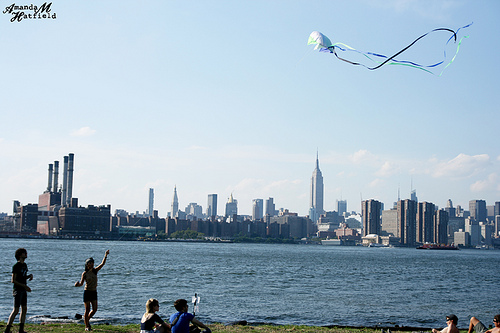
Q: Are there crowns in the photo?
A: No, there are no crowns.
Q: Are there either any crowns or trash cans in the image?
A: No, there are no crowns or trash cans.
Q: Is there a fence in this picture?
A: No, there are no fences.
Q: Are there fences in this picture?
A: No, there are no fences.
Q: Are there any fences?
A: No, there are no fences.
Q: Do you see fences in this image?
A: No, there are no fences.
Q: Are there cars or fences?
A: No, there are no fences or cars.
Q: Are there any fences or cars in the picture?
A: No, there are no fences or cars.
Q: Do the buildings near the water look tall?
A: Yes, the buildings are tall.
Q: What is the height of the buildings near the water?
A: The buildings are tall.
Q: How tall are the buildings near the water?
A: The buildings are tall.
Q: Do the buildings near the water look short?
A: No, the buildings are tall.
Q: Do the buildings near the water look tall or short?
A: The buildings are tall.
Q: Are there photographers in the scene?
A: Yes, there is a photographer.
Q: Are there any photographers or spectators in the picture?
A: Yes, there is a photographer.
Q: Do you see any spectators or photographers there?
A: Yes, there is a photographer.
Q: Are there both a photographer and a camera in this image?
A: No, there is a photographer but no cameras.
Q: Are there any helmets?
A: No, there are no helmets.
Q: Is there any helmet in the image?
A: No, there are no helmets.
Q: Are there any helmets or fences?
A: No, there are no helmets or fences.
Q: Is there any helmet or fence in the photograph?
A: No, there are no helmets or fences.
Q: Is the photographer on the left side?
A: Yes, the photographer is on the left of the image.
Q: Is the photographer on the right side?
A: No, the photographer is on the left of the image.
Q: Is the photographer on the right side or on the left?
A: The photographer is on the left of the image.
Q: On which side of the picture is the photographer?
A: The photographer is on the left of the image.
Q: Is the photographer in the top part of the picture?
A: Yes, the photographer is in the top of the image.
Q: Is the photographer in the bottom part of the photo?
A: No, the photographer is in the top of the image.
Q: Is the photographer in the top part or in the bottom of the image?
A: The photographer is in the top of the image.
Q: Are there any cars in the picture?
A: No, there are no cars.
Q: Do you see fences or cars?
A: No, there are no cars or fences.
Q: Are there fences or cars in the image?
A: No, there are no cars or fences.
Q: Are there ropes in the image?
A: No, there are no ropes.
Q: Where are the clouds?
A: The clouds are in the sky.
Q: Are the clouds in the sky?
A: Yes, the clouds are in the sky.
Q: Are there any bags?
A: No, there are no bags.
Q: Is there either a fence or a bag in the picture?
A: No, there are no bags or fences.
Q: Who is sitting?
A: The people are sitting.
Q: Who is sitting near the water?
A: The people are sitting near the water.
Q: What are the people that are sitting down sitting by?
A: The people are sitting by the water.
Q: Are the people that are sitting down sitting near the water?
A: Yes, the people are sitting near the water.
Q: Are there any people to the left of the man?
A: Yes, there are people to the left of the man.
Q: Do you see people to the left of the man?
A: Yes, there are people to the left of the man.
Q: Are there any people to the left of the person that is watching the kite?
A: Yes, there are people to the left of the man.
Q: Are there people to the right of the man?
A: No, the people are to the left of the man.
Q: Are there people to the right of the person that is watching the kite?
A: No, the people are to the left of the man.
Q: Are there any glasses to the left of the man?
A: No, there are people to the left of the man.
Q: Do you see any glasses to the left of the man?
A: No, there are people to the left of the man.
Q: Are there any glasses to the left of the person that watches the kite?
A: No, there are people to the left of the man.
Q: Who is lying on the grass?
A: The people are lying on the grass.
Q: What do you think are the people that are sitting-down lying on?
A: The people are lying on the grass.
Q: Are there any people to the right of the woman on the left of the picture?
A: Yes, there are people to the right of the woman.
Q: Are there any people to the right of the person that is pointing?
A: Yes, there are people to the right of the woman.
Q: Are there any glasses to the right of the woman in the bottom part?
A: No, there are people to the right of the woman.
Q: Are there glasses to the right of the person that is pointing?
A: No, there are people to the right of the woman.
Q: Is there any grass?
A: Yes, there is grass.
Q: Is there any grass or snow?
A: Yes, there is grass.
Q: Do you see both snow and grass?
A: No, there is grass but no snow.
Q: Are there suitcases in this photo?
A: No, there are no suitcases.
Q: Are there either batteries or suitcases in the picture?
A: No, there are no suitcases or batteries.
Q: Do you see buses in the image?
A: No, there are no buses.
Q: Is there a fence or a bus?
A: No, there are no buses or fences.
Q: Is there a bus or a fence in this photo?
A: No, there are no buses or fences.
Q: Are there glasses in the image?
A: No, there are no glasses.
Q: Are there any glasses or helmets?
A: No, there are no glasses or helmets.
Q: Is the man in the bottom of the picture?
A: Yes, the man is in the bottom of the image.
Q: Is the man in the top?
A: No, the man is in the bottom of the image.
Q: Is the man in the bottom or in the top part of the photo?
A: The man is in the bottom of the image.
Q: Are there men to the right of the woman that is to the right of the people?
A: Yes, there is a man to the right of the woman.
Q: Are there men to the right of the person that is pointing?
A: Yes, there is a man to the right of the woman.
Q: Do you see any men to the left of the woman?
A: No, the man is to the right of the woman.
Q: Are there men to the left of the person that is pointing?
A: No, the man is to the right of the woman.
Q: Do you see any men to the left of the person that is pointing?
A: No, the man is to the right of the woman.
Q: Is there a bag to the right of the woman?
A: No, there is a man to the right of the woman.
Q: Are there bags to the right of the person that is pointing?
A: No, there is a man to the right of the woman.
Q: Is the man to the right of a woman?
A: Yes, the man is to the right of a woman.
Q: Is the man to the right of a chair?
A: No, the man is to the right of a woman.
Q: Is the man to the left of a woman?
A: No, the man is to the right of a woman.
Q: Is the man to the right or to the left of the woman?
A: The man is to the right of the woman.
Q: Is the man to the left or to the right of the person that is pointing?
A: The man is to the right of the woman.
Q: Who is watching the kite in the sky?
A: The man is watching the kite.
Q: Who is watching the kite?
A: The man is watching the kite.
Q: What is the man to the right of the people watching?
A: The man is watching the kite.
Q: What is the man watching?
A: The man is watching the kite.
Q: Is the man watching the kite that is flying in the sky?
A: Yes, the man is watching the kite.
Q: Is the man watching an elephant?
A: No, the man is watching the kite.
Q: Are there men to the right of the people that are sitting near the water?
A: Yes, there is a man to the right of the people.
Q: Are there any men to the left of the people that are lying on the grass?
A: No, the man is to the right of the people.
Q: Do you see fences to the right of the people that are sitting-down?
A: No, there is a man to the right of the people.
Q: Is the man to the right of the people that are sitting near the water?
A: Yes, the man is to the right of the people.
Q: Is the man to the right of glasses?
A: No, the man is to the right of the people.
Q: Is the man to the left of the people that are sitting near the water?
A: No, the man is to the right of the people.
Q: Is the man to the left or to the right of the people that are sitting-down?
A: The man is to the right of the people.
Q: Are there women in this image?
A: Yes, there is a woman.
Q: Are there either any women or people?
A: Yes, there is a woman.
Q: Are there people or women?
A: Yes, there is a woman.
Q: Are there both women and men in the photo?
A: Yes, there are both a woman and a man.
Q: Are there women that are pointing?
A: Yes, there is a woman that is pointing.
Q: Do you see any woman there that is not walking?
A: Yes, there is a woman that is pointing .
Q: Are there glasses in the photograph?
A: No, there are no glasses.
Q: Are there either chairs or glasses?
A: No, there are no glasses or chairs.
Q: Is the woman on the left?
A: Yes, the woman is on the left of the image.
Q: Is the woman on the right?
A: No, the woman is on the left of the image.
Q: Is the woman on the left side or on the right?
A: The woman is on the left of the image.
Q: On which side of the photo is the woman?
A: The woman is on the left of the image.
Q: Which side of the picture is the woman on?
A: The woman is on the left of the image.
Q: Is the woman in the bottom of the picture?
A: Yes, the woman is in the bottom of the image.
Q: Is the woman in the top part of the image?
A: No, the woman is in the bottom of the image.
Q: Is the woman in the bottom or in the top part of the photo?
A: The woman is in the bottom of the image.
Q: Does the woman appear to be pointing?
A: Yes, the woman is pointing.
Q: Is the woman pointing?
A: Yes, the woman is pointing.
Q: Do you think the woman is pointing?
A: Yes, the woman is pointing.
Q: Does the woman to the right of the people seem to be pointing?
A: Yes, the woman is pointing.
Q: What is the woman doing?
A: The woman is pointing.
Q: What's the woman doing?
A: The woman is pointing.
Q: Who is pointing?
A: The woman is pointing.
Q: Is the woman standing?
A: No, the woman is pointing.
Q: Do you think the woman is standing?
A: No, the woman is pointing.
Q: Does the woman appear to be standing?
A: No, the woman is pointing.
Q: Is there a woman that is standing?
A: No, there is a woman but she is pointing.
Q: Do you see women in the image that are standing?
A: No, there is a woman but she is pointing.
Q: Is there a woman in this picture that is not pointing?
A: No, there is a woman but she is pointing.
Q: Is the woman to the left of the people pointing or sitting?
A: The woman is pointing.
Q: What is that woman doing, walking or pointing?
A: The woman is pointing.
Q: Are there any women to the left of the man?
A: Yes, there is a woman to the left of the man.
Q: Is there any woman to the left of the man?
A: Yes, there is a woman to the left of the man.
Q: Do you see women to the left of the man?
A: Yes, there is a woman to the left of the man.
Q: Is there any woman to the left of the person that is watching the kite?
A: Yes, there is a woman to the left of the man.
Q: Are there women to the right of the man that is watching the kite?
A: No, the woman is to the left of the man.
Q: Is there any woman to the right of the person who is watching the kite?
A: No, the woman is to the left of the man.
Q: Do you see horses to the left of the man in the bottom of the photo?
A: No, there is a woman to the left of the man.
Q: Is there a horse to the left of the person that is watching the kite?
A: No, there is a woman to the left of the man.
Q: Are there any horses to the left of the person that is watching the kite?
A: No, there is a woman to the left of the man.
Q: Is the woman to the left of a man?
A: Yes, the woman is to the left of a man.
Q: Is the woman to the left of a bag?
A: No, the woman is to the left of a man.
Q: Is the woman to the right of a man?
A: No, the woman is to the left of a man.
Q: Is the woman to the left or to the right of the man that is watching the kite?
A: The woman is to the left of the man.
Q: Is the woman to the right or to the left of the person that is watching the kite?
A: The woman is to the left of the man.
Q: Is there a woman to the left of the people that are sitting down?
A: Yes, there is a woman to the left of the people.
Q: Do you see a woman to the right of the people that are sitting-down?
A: No, the woman is to the left of the people.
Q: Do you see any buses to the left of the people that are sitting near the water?
A: No, there is a woman to the left of the people.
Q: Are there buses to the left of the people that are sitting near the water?
A: No, there is a woman to the left of the people.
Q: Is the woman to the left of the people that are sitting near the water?
A: Yes, the woman is to the left of the people.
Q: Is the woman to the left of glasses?
A: No, the woman is to the left of the people.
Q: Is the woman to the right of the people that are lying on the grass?
A: No, the woman is to the left of the people.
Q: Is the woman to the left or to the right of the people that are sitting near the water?
A: The woman is to the left of the people.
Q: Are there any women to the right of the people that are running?
A: Yes, there is a woman to the right of the people.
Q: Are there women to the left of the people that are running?
A: No, the woman is to the right of the people.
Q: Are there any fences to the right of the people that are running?
A: No, there is a woman to the right of the people.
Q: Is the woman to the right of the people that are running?
A: Yes, the woman is to the right of the people.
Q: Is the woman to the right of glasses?
A: No, the woman is to the right of the people.